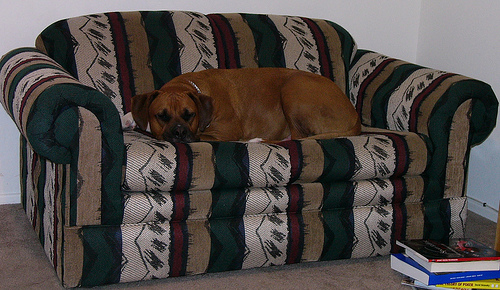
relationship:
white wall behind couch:
[385, 10, 473, 45] [0, 10, 499, 289]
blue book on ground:
[390, 254, 499, 286] [0, 204, 495, 287]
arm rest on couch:
[347, 48, 499, 153] [7, 8, 484, 260]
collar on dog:
[187, 79, 203, 94] [132, 69, 361, 145]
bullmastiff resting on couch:
[130, 67, 362, 144] [0, 10, 500, 290]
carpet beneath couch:
[327, 254, 392, 288] [7, 8, 484, 260]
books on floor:
[383, 237, 499, 288] [0, 195, 497, 288]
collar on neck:
[188, 80, 202, 94] [163, 74, 215, 141]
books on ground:
[383, 237, 499, 288] [0, 204, 495, 287]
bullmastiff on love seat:
[130, 67, 362, 144] [0, 10, 500, 290]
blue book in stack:
[390, 254, 499, 281] [390, 236, 499, 288]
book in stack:
[435, 279, 499, 290] [390, 236, 499, 288]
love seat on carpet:
[0, 10, 500, 290] [4, 184, 494, 289]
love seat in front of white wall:
[6, 11, 488, 258] [1, 2, 440, 205]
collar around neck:
[188, 80, 202, 94] [170, 80, 219, 134]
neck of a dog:
[170, 80, 219, 134] [132, 69, 361, 145]